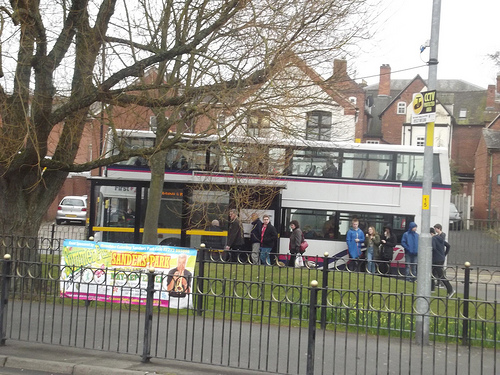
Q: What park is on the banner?
A: Sanders.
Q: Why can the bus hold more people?
A: It is double decker.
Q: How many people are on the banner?
A: One.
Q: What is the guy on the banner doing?
A: Playing trumpet.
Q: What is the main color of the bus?
A: White.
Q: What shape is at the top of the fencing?
A: Circle.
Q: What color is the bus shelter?
A: Black.